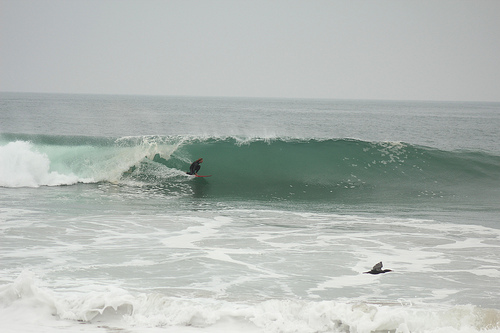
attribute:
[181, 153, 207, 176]
surfer — male, shooting pipeline, surfing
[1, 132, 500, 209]
wave — white, crashing down, about to curl over, blue, small, crashing, curled, wind swept, water, crested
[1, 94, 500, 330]
ocean — rippling, calm, water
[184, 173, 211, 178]
board — orange, red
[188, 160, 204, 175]
wetsuit — black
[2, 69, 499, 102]
horizon — in distance, vast, calm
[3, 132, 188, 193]
upper crest — whitecap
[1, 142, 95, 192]
foam — white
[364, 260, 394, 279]
bird — in flight, dark colored, flying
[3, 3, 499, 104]
sky — cloudy, blue gray, hazy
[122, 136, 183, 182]
curl — green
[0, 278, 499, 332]
wave — near shore